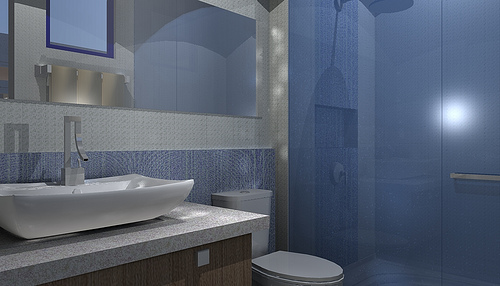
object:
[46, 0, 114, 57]
window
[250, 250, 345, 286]
seat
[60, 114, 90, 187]
faucet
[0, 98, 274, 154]
stripe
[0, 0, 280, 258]
wall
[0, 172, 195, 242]
sink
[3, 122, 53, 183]
shadow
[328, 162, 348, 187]
handle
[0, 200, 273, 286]
counter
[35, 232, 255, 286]
wood sink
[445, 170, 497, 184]
bar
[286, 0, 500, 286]
shower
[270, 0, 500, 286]
door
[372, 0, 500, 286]
bathroom walls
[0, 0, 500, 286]
bathroom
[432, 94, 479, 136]
glare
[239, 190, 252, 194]
button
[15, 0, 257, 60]
shadow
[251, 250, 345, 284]
lid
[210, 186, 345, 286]
toilet